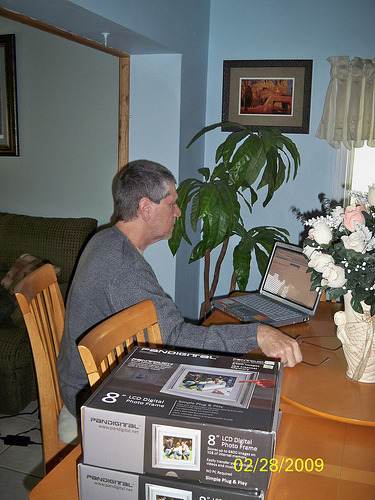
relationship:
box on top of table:
[80, 345, 283, 492] [27, 289, 374, 497]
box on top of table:
[76, 459, 265, 498] [27, 289, 374, 497]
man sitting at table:
[56, 158, 302, 421] [27, 289, 374, 497]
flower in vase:
[319, 261, 348, 290] [330, 286, 373, 384]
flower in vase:
[336, 201, 365, 233] [330, 286, 373, 384]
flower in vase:
[309, 219, 332, 246] [330, 286, 373, 384]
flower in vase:
[339, 231, 366, 254] [330, 286, 373, 384]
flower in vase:
[306, 248, 335, 272] [330, 286, 373, 384]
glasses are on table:
[268, 330, 341, 366] [27, 289, 374, 497]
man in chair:
[69, 162, 242, 367] [3, 270, 97, 416]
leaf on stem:
[190, 172, 249, 204] [203, 234, 258, 298]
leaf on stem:
[187, 244, 234, 278] [188, 177, 221, 226]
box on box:
[111, 395, 233, 434] [87, 475, 126, 489]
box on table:
[76, 459, 265, 499] [313, 457, 359, 484]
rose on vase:
[314, 258, 346, 289] [351, 315, 368, 358]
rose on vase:
[302, 244, 315, 260] [343, 320, 373, 354]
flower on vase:
[309, 217, 333, 246] [335, 318, 363, 358]